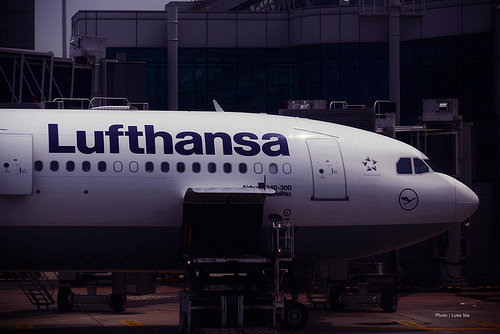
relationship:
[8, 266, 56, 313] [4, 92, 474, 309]
stairs on side of plane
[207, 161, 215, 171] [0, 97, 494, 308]
window on vehicle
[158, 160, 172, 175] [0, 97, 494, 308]
window on vehicle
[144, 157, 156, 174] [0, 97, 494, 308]
window on vehicle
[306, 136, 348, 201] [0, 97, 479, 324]
door on side of plane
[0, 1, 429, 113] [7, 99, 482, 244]
hangar with plane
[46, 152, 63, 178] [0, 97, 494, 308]
window on vehicle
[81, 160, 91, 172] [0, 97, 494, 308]
window on a vehicle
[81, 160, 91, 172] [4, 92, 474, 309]
window on plane